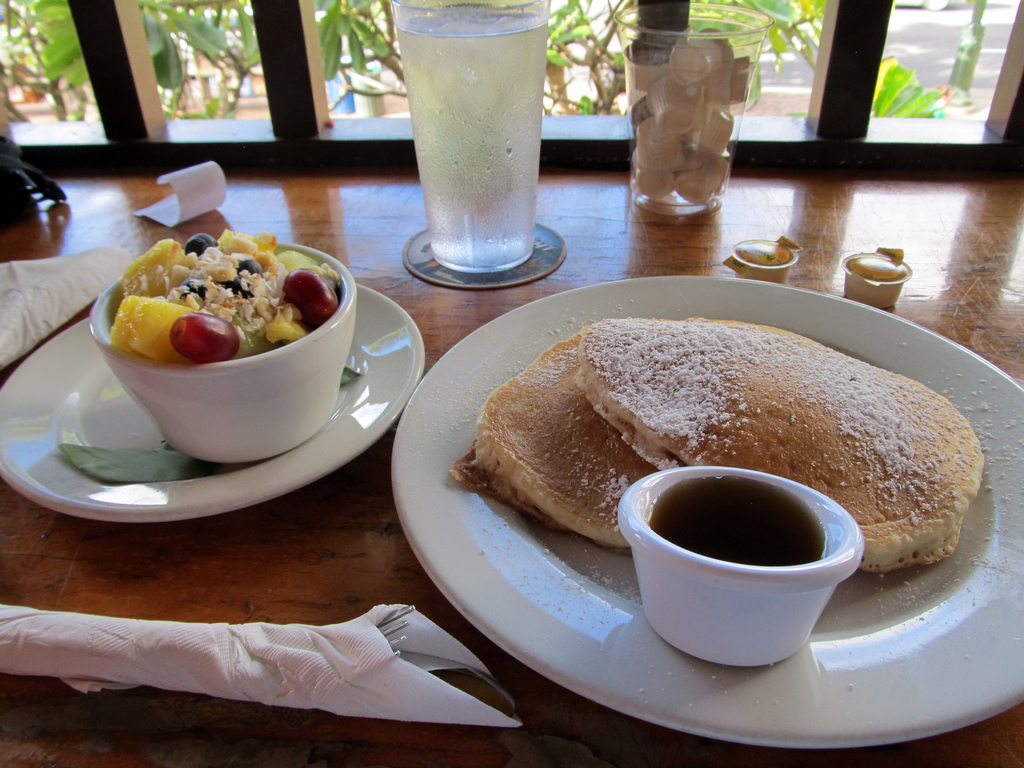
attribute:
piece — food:
[182, 230, 215, 263]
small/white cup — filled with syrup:
[610, 452, 870, 666]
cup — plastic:
[637, 10, 728, 201]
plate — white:
[408, 268, 912, 744]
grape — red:
[172, 313, 242, 368]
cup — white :
[615, 466, 862, 672]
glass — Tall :
[386, 1, 555, 269]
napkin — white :
[12, 602, 518, 734]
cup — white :
[101, 230, 363, 470]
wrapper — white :
[134, 161, 225, 228]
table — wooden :
[10, 159, 1017, 758]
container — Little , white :
[615, 457, 860, 671]